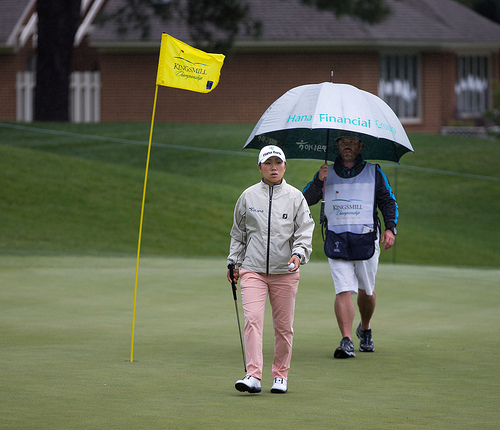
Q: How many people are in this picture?
A: 2.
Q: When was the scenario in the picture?
A: During the day.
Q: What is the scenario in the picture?
A: A golf course.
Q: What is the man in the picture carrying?
A: An umbrella.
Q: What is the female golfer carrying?
A: A club and golf ball.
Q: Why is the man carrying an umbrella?
A: It's raining out.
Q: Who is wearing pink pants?
A: The female golfer.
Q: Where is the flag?
A: In a hole to the left of the man and golfer.